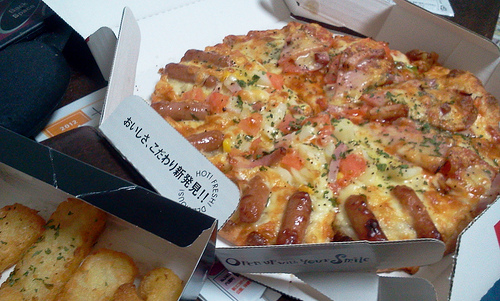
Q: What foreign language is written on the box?
A: Japanese.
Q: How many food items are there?
A: Two.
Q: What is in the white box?
A: A pizza.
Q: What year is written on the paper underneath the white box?
A: 2012.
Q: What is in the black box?
A: Garlic breadsticks.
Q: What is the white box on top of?
A: A newspaper.